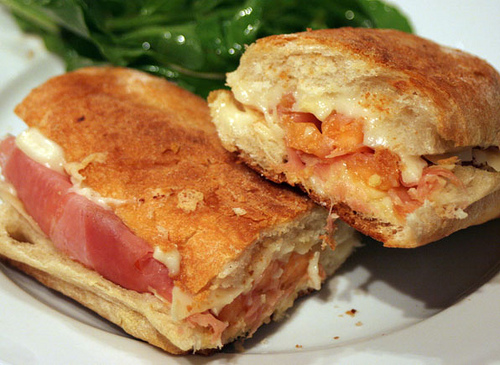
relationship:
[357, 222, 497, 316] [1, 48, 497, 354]
shadow on white plate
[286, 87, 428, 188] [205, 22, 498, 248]
cheese in bun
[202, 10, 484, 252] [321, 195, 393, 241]
bread has crispy edge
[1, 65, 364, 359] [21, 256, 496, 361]
sandwich on white plate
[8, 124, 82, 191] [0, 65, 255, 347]
melted cheese inside sandwich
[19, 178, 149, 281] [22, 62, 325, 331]
meat inside sandwich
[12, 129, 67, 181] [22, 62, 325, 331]
cheese inside sandwich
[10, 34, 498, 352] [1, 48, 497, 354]
sandwich on white plate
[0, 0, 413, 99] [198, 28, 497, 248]
green vegetable next to sandwich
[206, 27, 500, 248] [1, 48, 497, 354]
sandwich on white plate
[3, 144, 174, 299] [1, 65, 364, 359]
ham on sandwich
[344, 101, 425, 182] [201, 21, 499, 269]
cheese on sandwich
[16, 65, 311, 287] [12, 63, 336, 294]
crust on bread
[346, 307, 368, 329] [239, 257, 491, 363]
bread crumbs on plate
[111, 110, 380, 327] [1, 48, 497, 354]
food on white plate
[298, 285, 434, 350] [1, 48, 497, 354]
crumbs on white plate